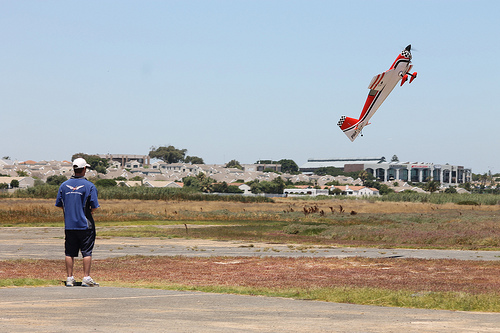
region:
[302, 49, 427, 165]
small model plane in air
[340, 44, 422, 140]
red and white plane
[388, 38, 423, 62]
small propeller on nose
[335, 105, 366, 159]
red and white tail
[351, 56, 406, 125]
black stripe on plane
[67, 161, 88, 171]
man has white hat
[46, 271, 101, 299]
man has white shoes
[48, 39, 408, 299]
man is controlling plane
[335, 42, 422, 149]
a red and white plane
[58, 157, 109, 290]
a man standing watching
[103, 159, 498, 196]
houses in the distance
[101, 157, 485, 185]
white houses in the distance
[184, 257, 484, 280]
brown grass on the ground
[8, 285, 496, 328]
a concrete slab on the ground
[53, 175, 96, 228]
a blue tee shirt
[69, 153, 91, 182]
a white hat on a mans head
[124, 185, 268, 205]
dark green grass in the field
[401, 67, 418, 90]
red wheels on a plane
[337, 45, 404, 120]
remote controlled airplane taking off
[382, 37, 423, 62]
propeller on front of plane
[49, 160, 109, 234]
blue shirt on man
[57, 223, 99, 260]
black shorts on man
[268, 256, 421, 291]
red grass on field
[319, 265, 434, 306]
green grass by runway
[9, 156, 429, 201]
tall buildings in the distance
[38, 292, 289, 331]
paved ground under man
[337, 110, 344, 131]
red tail of plane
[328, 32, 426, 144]
kite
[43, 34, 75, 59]
white clouds in blue sky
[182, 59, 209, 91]
white clouds in blue sky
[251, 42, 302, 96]
white clouds in blue sky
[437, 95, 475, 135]
white clouds in blue sky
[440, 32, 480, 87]
white clouds in blue sky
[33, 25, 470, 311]
A person is using a model plane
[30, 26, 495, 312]
A person is wearing dark shorts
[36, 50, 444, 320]
A person is wearing a hat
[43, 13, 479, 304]
A small plane is up in the air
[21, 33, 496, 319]
A person is close to a city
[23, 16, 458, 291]
A person is out in the daytime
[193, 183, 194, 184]
A green leaf on a plant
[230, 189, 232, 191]
A green leaf on a plant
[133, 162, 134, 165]
A window on a building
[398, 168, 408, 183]
A window on a building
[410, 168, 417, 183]
A window on a building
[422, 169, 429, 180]
A window on a building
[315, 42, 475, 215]
a plane in the air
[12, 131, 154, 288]
a man standing outside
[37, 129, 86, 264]
a man wearing a hat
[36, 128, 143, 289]
a man wearing a shirt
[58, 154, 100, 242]
a man wearing a blue shirt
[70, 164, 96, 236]
a man wearing shorts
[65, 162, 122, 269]
a man wearing black shorts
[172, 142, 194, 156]
green leaves o nthe tree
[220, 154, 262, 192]
green leaves o nthe tree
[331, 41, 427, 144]
a large red and white plane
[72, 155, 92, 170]
a white baseball cap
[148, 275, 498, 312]
a section of green grass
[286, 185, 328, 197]
a small white building